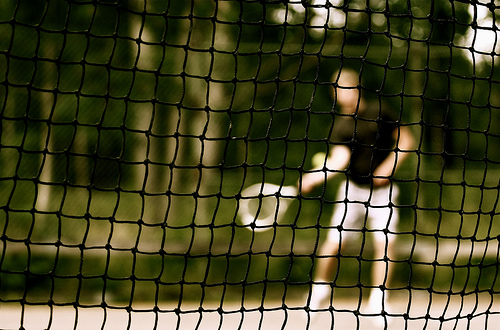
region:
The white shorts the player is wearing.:
[332, 184, 402, 249]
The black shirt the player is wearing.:
[318, 111, 405, 174]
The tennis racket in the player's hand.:
[230, 173, 313, 230]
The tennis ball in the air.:
[302, 153, 332, 168]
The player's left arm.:
[290, 151, 347, 193]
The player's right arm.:
[379, 129, 415, 183]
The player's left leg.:
[306, 241, 340, 285]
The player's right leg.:
[361, 232, 394, 292]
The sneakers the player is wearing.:
[296, 286, 403, 306]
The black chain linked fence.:
[1, 9, 497, 329]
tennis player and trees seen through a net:
[9, 8, 488, 313]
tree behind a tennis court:
[10, 5, 107, 227]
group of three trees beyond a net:
[111, 0, 241, 247]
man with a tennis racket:
[241, 62, 427, 328]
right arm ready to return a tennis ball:
[230, 116, 356, 238]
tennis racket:
[230, 176, 327, 248]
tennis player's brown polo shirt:
[323, 102, 420, 187]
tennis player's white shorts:
[322, 179, 404, 248]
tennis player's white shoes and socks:
[291, 273, 401, 328]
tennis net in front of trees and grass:
[5, 161, 219, 319]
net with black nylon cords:
[0, 0, 497, 327]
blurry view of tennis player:
[236, 56, 426, 316]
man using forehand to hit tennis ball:
[226, 171, 316, 233]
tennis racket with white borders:
[227, 172, 310, 234]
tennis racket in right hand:
[235, 172, 308, 234]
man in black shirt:
[293, 67, 417, 317]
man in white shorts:
[301, 57, 416, 312]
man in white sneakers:
[296, 64, 415, 309]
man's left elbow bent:
[373, 111, 423, 185]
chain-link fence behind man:
[0, 38, 498, 287]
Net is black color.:
[88, 78, 490, 280]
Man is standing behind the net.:
[209, 66, 416, 320]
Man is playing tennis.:
[203, 64, 413, 306]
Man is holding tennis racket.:
[235, 146, 312, 239]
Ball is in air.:
[307, 146, 333, 178]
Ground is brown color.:
[75, 307, 275, 328]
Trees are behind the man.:
[24, 31, 329, 168]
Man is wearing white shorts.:
[326, 185, 399, 242]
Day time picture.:
[10, 19, 476, 319]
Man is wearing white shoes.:
[293, 276, 390, 326]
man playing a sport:
[225, 54, 443, 278]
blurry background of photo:
[250, 66, 420, 246]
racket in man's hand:
[218, 168, 306, 245]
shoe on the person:
[282, 257, 349, 327]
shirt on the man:
[331, 101, 426, 183]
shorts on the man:
[301, 168, 413, 273]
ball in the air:
[296, 138, 338, 185]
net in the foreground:
[112, 90, 218, 215]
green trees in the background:
[208, 75, 290, 164]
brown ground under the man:
[322, 308, 354, 328]